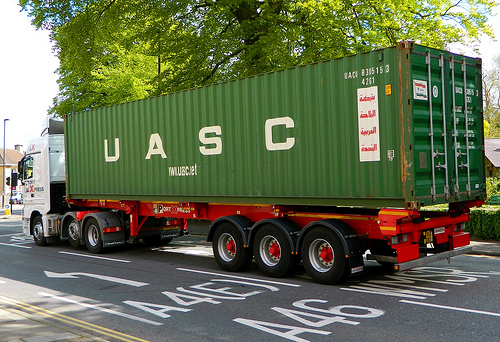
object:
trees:
[46, 0, 207, 117]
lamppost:
[1, 118, 13, 205]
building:
[0, 145, 33, 197]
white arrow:
[43, 267, 149, 289]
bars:
[426, 49, 471, 201]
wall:
[411, 47, 484, 203]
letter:
[103, 137, 121, 163]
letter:
[197, 125, 224, 157]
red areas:
[358, 215, 470, 257]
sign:
[356, 85, 378, 161]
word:
[358, 140, 377, 155]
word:
[358, 125, 377, 136]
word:
[357, 88, 376, 103]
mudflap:
[343, 239, 367, 277]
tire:
[251, 222, 300, 276]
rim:
[67, 221, 80, 242]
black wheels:
[32, 216, 346, 287]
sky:
[0, 8, 71, 113]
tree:
[11, 0, 495, 94]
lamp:
[0, 116, 12, 217]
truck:
[20, 40, 486, 286]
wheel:
[211, 222, 243, 273]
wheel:
[83, 216, 105, 251]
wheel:
[65, 217, 82, 246]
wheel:
[29, 213, 46, 245]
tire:
[296, 220, 363, 282]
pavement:
[145, 270, 279, 327]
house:
[482, 135, 499, 172]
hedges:
[487, 175, 499, 200]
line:
[177, 266, 299, 286]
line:
[399, 297, 499, 315]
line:
[59, 250, 130, 262]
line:
[0, 242, 30, 248]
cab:
[19, 116, 64, 236]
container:
[64, 40, 486, 208]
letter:
[264, 116, 295, 152]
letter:
[144, 132, 167, 160]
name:
[102, 116, 297, 164]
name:
[359, 93, 376, 103]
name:
[360, 109, 377, 119]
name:
[361, 143, 378, 153]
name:
[168, 163, 200, 177]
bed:
[63, 197, 483, 265]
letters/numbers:
[230, 297, 382, 342]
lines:
[21, 300, 101, 336]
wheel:
[58, 208, 85, 246]